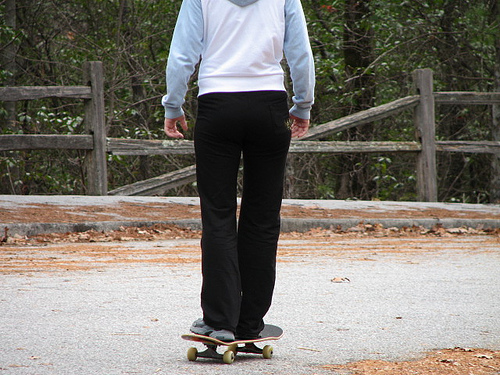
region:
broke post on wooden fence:
[302, 89, 420, 139]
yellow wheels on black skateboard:
[179, 322, 284, 362]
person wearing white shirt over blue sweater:
[157, 0, 327, 141]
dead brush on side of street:
[4, 242, 169, 280]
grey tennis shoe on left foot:
[185, 311, 236, 346]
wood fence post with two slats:
[407, 63, 443, 205]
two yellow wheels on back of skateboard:
[182, 339, 236, 365]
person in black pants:
[168, 0, 313, 364]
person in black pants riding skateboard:
[164, 1, 315, 368]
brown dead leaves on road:
[367, 346, 493, 373]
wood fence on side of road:
[414, 69, 492, 199]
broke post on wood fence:
[339, 84, 424, 133]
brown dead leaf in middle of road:
[325, 270, 357, 289]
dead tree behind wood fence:
[48, 23, 152, 142]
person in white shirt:
[157, 1, 317, 338]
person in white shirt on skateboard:
[161, 2, 314, 362]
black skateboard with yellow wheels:
[182, 318, 284, 366]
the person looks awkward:
[75, 35, 440, 330]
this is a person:
[137, 32, 357, 310]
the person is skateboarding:
[151, 27, 343, 289]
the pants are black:
[193, 104, 295, 271]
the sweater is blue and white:
[157, 15, 354, 107]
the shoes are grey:
[172, 300, 236, 352]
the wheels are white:
[183, 340, 250, 372]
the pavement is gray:
[30, 285, 177, 370]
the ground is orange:
[13, 227, 173, 299]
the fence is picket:
[34, 71, 154, 225]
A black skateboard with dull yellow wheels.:
[177, 324, 282, 361]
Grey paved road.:
[2, 239, 499, 371]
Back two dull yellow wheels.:
[186, 347, 234, 361]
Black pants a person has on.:
[194, 90, 293, 335]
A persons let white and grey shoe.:
[191, 318, 236, 342]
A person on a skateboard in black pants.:
[160, 1, 315, 341]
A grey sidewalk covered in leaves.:
[0, 193, 498, 234]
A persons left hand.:
[164, 111, 189, 139]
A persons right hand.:
[288, 107, 309, 138]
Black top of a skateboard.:
[182, 323, 283, 343]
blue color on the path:
[13, 298, 120, 343]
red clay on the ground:
[398, 359, 459, 368]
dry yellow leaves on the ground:
[80, 225, 132, 238]